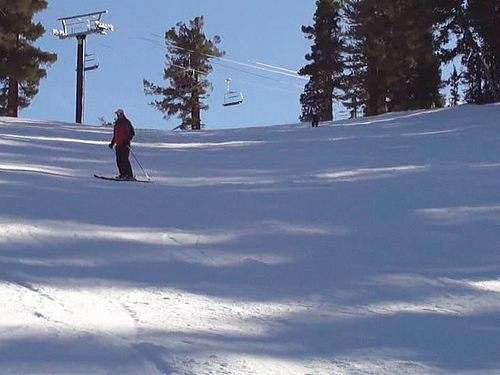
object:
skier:
[107, 108, 136, 180]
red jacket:
[108, 117, 136, 149]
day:
[0, 0, 499, 375]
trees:
[296, 0, 351, 125]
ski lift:
[80, 54, 102, 73]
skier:
[307, 98, 323, 127]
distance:
[273, 72, 498, 135]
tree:
[141, 15, 223, 130]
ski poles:
[125, 145, 152, 182]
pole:
[50, 10, 114, 124]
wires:
[144, 38, 308, 81]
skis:
[94, 175, 153, 184]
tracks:
[0, 223, 393, 375]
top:
[0, 104, 500, 137]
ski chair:
[221, 78, 244, 107]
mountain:
[225, 84, 500, 132]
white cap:
[115, 109, 124, 114]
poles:
[5, 11, 18, 120]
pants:
[114, 143, 134, 176]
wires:
[119, 28, 294, 72]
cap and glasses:
[114, 108, 124, 116]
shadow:
[0, 98, 500, 375]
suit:
[108, 108, 137, 179]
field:
[0, 103, 500, 375]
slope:
[0, 102, 500, 368]